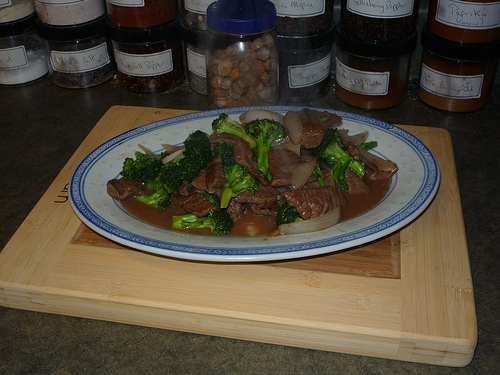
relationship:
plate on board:
[80, 96, 450, 269] [9, 87, 493, 369]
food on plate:
[139, 132, 376, 216] [80, 96, 450, 269]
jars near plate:
[0, 1, 499, 115] [80, 96, 450, 269]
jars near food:
[0, 1, 499, 115] [139, 132, 376, 216]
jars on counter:
[0, 1, 499, 115] [1, 84, 500, 370]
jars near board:
[0, 1, 499, 115] [9, 87, 493, 369]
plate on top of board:
[80, 96, 450, 269] [9, 87, 493, 369]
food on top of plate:
[139, 132, 376, 216] [80, 96, 450, 269]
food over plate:
[139, 132, 376, 216] [80, 96, 450, 269]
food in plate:
[139, 132, 376, 216] [80, 96, 450, 269]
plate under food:
[80, 96, 450, 269] [139, 132, 376, 216]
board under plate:
[9, 87, 493, 369] [80, 96, 450, 269]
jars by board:
[0, 1, 499, 115] [9, 87, 493, 369]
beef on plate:
[108, 106, 398, 236] [80, 96, 450, 269]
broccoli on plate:
[121, 110, 373, 232] [80, 96, 450, 269]